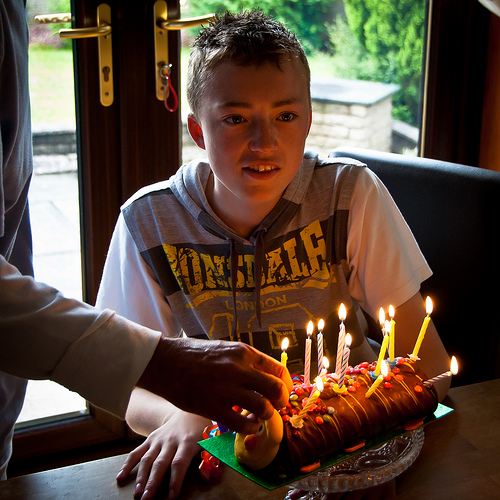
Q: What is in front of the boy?
A: A cake with candles.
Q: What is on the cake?
A: Candles and M&Ms.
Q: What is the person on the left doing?
A: Lighting the candles.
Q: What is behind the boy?
A: Double doors.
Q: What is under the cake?
A: A glass plate.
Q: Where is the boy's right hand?
A: On the table.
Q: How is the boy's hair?
A: Spiked.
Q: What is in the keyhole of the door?
A: A key.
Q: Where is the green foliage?
A: Outside the window.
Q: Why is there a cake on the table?
A: It's the boy's birthday.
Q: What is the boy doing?
A: Seeing.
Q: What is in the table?
A: Cake.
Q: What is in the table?
A: Candles.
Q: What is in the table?
A: Food.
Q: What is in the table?
A: Cake.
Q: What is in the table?
A: Candle.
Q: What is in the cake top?
A: Candles.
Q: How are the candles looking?
A: Burning.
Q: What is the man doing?
A: Looking.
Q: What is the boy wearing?
A: Shirt.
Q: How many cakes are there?
A: One.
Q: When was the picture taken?
A: Daytime.